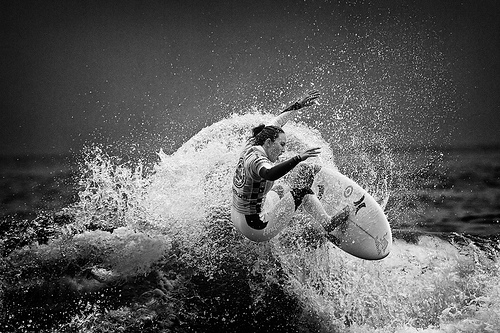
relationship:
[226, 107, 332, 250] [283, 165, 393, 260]
man on surf board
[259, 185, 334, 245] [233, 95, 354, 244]
pants on woman